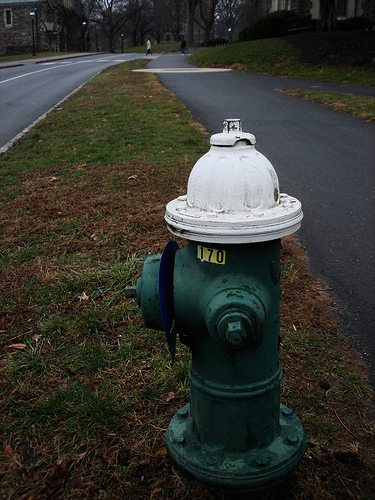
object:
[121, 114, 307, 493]
hydrant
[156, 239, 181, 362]
disk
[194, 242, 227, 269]
number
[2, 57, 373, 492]
grass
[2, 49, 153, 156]
road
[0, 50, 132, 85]
line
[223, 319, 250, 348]
bolt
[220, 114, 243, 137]
bolt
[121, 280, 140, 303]
bolt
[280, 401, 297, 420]
bolt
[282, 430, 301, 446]
bolt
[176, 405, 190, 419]
bolt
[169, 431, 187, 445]
bolt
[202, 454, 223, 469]
bolt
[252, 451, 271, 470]
bolt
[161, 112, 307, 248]
cap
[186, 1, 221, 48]
tree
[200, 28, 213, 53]
trunk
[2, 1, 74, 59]
building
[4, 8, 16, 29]
window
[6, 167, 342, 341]
dry grass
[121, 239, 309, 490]
base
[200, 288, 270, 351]
plug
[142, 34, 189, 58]
people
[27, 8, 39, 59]
lamp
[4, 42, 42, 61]
bushes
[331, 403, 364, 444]
twig